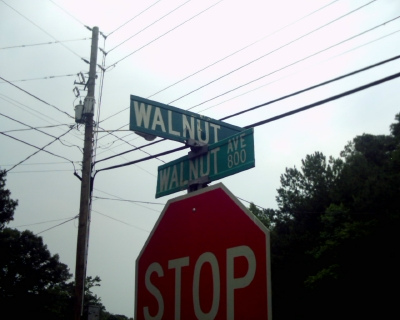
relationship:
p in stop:
[225, 244, 254, 318] [143, 242, 255, 316]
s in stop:
[135, 248, 185, 314] [143, 242, 255, 316]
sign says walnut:
[129, 92, 241, 149] [133, 99, 222, 142]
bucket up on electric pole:
[73, 102, 85, 124] [67, 27, 102, 319]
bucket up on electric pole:
[79, 93, 96, 117] [67, 27, 102, 319]